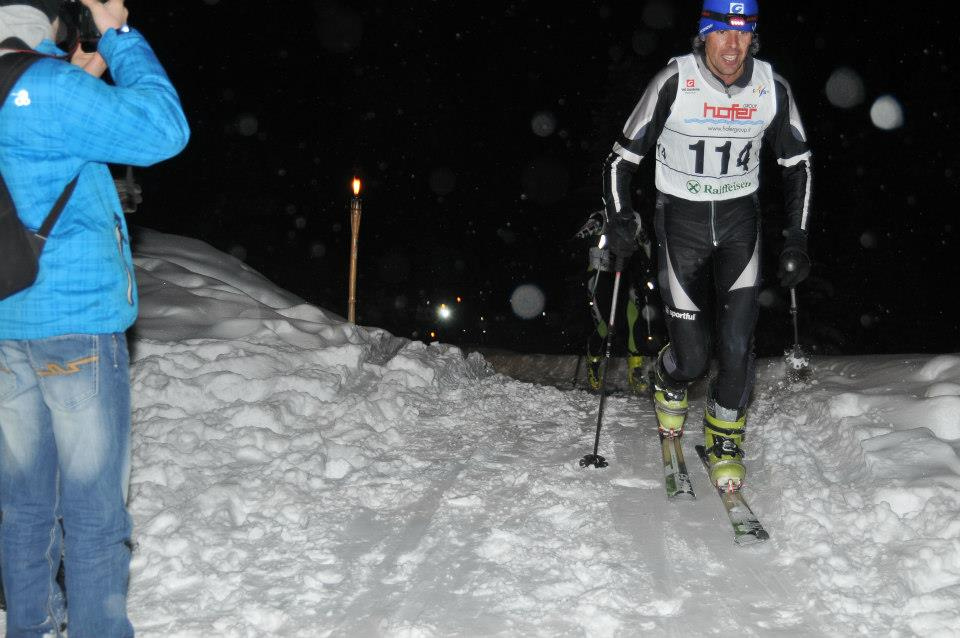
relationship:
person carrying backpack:
[0, 2, 190, 634] [2, 50, 84, 295]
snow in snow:
[0, 231, 960, 638] [108, 222, 954, 637]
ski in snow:
[660, 436, 697, 501] [108, 222, 954, 637]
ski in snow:
[695, 432, 780, 545] [108, 222, 954, 637]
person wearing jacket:
[0, 2, 190, 634] [3, 20, 192, 340]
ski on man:
[660, 436, 697, 501] [575, 1, 814, 547]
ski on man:
[694, 444, 769, 545] [575, 1, 814, 547]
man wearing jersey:
[575, 1, 814, 547] [652, 52, 779, 198]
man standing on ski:
[593, 1, 817, 494] [695, 432, 780, 545]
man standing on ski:
[593, 1, 817, 494] [656, 432, 701, 506]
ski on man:
[653, 436, 699, 501] [593, 1, 817, 494]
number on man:
[690, 140, 754, 175] [593, 1, 817, 494]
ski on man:
[694, 444, 769, 545] [593, 1, 817, 494]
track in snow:
[342, 341, 839, 622] [108, 222, 954, 637]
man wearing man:
[593, 1, 817, 494] [575, 1, 814, 547]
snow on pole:
[108, 222, 954, 637] [582, 229, 638, 473]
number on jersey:
[690, 140, 754, 175] [652, 52, 779, 198]